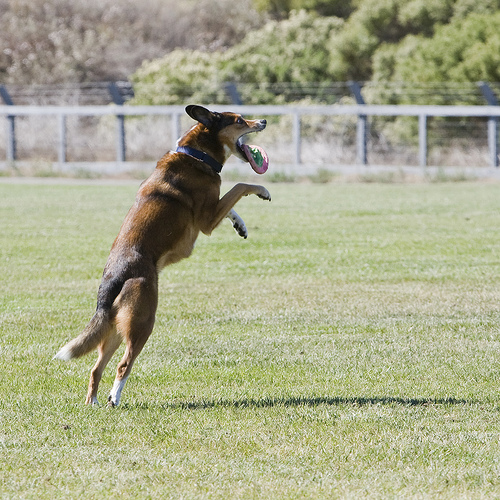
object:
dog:
[51, 91, 283, 407]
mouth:
[236, 118, 273, 175]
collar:
[171, 140, 224, 173]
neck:
[179, 126, 228, 170]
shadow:
[169, 392, 478, 412]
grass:
[0, 172, 500, 500]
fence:
[0, 82, 500, 170]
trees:
[355, 0, 500, 167]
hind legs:
[107, 275, 160, 408]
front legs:
[199, 182, 272, 236]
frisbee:
[243, 140, 270, 174]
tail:
[49, 286, 119, 365]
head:
[182, 102, 271, 175]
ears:
[184, 103, 221, 131]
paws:
[253, 185, 273, 202]